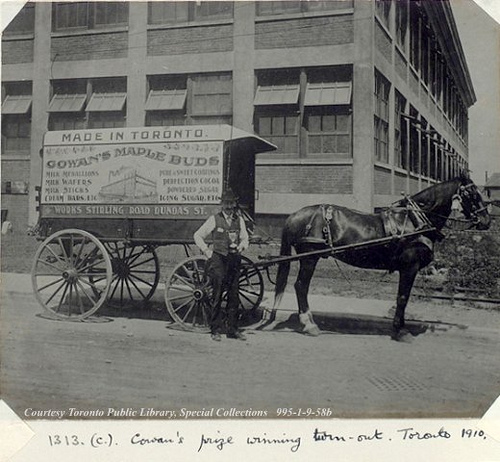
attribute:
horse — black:
[273, 171, 490, 344]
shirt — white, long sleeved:
[190, 209, 251, 256]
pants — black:
[179, 242, 277, 331]